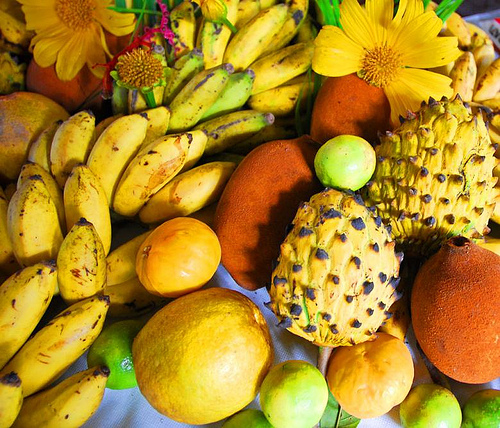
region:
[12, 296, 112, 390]
this is a banana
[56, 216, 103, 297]
this is a banana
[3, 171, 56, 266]
this is a banana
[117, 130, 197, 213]
this is a banana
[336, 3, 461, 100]
this is a yellow flower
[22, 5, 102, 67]
this is a yellow flower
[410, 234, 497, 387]
this is an orange fruit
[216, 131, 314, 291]
this is an orange fruit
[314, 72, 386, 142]
this is an orange fruit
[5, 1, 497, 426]
these are different types of fruit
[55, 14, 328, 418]
a stall of fruits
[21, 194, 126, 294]
bananas are rippen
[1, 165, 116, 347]
bananas are dark yellow in color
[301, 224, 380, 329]
the fruit is rippen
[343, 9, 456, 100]
the flower petals are yellow in color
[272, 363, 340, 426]
the oarnage is green in color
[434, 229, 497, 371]
the fruit is maroon in color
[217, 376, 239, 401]
part of a fruit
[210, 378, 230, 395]
aprt of a peel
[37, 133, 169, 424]
small bananas in bunch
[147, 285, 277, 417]
large orange in fruits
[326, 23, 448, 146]
yellow flower in fruits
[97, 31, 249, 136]
small and green bananas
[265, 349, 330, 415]
small and yellow fruit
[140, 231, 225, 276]
small and orange fruit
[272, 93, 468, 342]
yellow durians in pile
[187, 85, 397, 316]
dark brown fruits in pile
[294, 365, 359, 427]
green leaves behind fruit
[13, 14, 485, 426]
large pile of fruits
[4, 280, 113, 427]
A fresh ripe yellow banana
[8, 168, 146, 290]
A fresh ripe yellow banana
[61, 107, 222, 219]
A fresh ripe yellow banana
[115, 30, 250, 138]
A fresh ripe yellow banana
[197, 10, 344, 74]
A fresh ripe yellow banana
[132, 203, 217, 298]
A fresh yellow orange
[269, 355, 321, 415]
A fresh yellow orange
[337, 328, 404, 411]
A fresh yellow orange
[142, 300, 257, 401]
A fresh yellow orange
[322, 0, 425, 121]
A beautiful yellow flower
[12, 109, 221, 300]
bunch of bananas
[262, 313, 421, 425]
green lime by orange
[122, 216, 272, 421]
small orange by large orange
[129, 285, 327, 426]
large orange by green lime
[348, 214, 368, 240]
purple spot on fruit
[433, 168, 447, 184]
purple spot on fruit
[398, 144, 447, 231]
purple spots on fruit